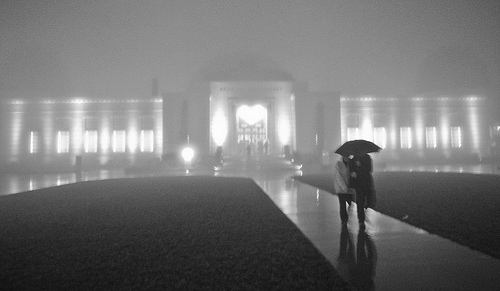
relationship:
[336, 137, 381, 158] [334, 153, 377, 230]
umbrella above people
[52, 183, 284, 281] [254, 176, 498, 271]
grass beside sidewalk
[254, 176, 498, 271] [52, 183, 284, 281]
sidewalk near grass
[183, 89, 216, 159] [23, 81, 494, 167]
pillars on building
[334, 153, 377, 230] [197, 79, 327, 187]
people in front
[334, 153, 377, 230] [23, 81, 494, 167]
people near building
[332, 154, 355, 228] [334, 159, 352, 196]
man has coat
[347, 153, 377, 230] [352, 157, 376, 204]
people wearing clothes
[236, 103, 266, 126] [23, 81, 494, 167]
lights in building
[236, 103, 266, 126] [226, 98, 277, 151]
lights in entrance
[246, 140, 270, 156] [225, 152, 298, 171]
people are in door step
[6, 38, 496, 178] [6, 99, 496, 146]
building being lit up by lights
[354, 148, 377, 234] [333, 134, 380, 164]
man walking under umbrella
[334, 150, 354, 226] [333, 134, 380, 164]
woman walking under umbrella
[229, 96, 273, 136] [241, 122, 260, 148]
window above door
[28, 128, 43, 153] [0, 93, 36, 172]
window front building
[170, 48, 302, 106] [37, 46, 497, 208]
words above building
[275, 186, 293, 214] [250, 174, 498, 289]
refelction on sidewalk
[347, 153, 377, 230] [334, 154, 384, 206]
people are wearing jackets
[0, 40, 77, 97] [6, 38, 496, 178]
dome on building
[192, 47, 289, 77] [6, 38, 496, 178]
dome on building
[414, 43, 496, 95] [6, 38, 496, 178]
dome on building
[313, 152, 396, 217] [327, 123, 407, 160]
couple under umbrella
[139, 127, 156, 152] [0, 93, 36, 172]
window on building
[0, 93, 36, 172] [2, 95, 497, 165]
building behind pillars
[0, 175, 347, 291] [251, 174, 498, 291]
grass next to sidewalk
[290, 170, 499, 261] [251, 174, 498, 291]
grass next to sidewalk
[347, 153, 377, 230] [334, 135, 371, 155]
people sharing umbrella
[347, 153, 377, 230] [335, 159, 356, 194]
people wearing coat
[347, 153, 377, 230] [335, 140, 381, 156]
people under umbrella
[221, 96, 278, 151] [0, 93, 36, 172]
entrance leading to building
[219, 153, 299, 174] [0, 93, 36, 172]
stairs leading to building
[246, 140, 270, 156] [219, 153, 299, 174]
people walking on stairs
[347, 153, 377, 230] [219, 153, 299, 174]
people walking on stairs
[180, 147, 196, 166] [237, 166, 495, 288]
light shining on pavement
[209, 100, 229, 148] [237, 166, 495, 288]
light shining on pavement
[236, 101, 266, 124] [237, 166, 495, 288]
light shining on pavement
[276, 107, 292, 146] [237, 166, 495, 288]
light shining on pavement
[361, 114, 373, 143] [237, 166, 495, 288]
light shining on pavement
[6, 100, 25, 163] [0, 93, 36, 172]
light shining on building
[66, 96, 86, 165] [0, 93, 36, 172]
light shining on building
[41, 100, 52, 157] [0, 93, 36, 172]
light shining on building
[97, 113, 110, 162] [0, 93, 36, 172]
light shining on building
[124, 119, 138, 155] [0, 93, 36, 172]
light shining on building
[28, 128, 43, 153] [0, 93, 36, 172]
window built into building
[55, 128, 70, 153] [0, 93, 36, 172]
window built into building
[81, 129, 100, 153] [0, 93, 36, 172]
window built into building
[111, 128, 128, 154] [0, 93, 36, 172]
window built into building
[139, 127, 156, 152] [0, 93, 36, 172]
window built into building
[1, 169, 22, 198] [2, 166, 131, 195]
light reflecting on walkway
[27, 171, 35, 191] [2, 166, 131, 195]
light reflecting on walkway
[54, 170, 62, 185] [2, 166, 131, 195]
light reflecting on walkway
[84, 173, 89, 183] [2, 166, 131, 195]
light reflecting on walkway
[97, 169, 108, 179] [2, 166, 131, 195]
light reflecting on walkway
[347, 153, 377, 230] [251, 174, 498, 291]
people walking on sidewalk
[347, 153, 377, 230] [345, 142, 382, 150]
people holding umbrella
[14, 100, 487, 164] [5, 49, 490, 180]
wall supporting building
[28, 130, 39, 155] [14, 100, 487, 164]
window built into wall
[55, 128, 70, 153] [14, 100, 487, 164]
window built into wall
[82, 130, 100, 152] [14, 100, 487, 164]
window built into wall